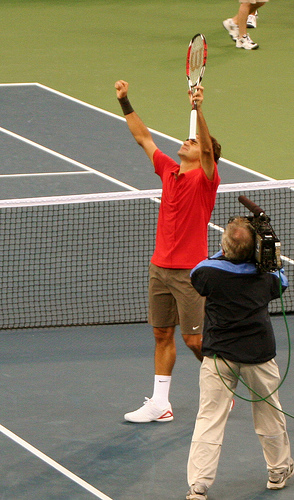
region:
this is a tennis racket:
[185, 33, 208, 140]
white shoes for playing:
[122, 400, 176, 421]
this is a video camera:
[245, 190, 281, 266]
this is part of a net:
[3, 198, 96, 291]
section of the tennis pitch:
[5, 424, 173, 494]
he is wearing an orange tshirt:
[147, 133, 220, 263]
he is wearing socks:
[149, 359, 166, 395]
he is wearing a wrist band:
[115, 93, 136, 118]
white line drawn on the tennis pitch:
[3, 426, 56, 474]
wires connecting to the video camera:
[221, 362, 271, 406]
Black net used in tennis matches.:
[0, 207, 93, 329]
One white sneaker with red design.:
[123, 401, 175, 422]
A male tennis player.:
[102, 23, 221, 423]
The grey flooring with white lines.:
[0, 81, 89, 193]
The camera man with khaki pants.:
[182, 194, 292, 497]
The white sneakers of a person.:
[221, 0, 267, 49]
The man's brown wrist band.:
[117, 97, 137, 115]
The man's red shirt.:
[151, 152, 219, 270]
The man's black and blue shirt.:
[190, 257, 287, 363]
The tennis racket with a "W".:
[184, 34, 207, 133]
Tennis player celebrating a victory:
[92, 13, 240, 438]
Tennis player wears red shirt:
[87, 68, 236, 446]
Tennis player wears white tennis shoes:
[103, 69, 237, 435]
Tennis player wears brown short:
[101, 70, 246, 427]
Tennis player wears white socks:
[113, 365, 237, 429]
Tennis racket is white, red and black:
[175, 26, 211, 146]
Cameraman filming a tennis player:
[182, 183, 292, 498]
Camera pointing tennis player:
[228, 194, 290, 277]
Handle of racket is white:
[182, 107, 200, 143]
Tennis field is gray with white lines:
[0, 72, 293, 497]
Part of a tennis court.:
[4, 117, 106, 188]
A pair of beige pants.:
[192, 347, 292, 490]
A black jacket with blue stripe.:
[191, 252, 284, 362]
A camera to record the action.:
[238, 193, 285, 275]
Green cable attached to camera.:
[213, 250, 287, 410]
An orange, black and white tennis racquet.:
[179, 22, 211, 139]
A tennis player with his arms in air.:
[111, 36, 219, 263]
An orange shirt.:
[152, 141, 212, 270]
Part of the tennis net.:
[6, 191, 133, 327]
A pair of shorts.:
[140, 259, 204, 335]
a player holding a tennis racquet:
[101, 38, 221, 287]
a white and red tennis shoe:
[116, 393, 180, 421]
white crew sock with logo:
[151, 373, 180, 399]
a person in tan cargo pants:
[191, 348, 292, 468]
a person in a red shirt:
[148, 146, 220, 258]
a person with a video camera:
[203, 189, 287, 283]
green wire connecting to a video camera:
[263, 259, 289, 360]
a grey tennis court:
[49, 348, 126, 396]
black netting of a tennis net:
[35, 225, 126, 293]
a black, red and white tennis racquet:
[180, 34, 208, 97]